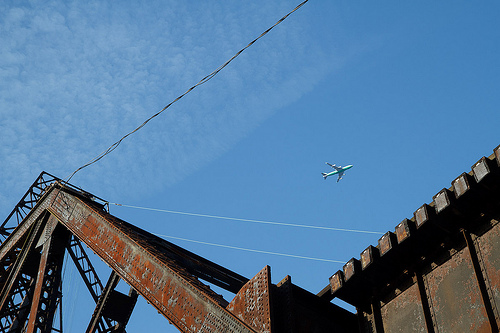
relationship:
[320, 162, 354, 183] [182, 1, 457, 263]
airplane in sky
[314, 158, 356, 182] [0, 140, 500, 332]
airplane above building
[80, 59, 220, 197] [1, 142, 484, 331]
cable on bridge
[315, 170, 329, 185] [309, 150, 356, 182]
tail of plane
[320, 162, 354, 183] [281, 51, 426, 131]
airplane in sky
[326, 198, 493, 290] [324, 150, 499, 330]
roof of building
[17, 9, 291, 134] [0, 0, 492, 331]
clouds in sky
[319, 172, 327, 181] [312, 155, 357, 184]
tail of plane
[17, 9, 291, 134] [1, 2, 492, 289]
clouds in sky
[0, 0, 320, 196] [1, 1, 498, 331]
white clouds in blue sky